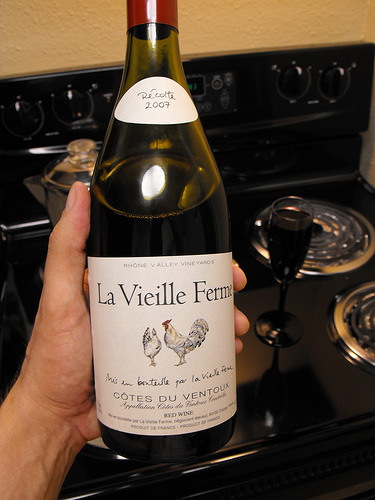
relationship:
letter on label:
[92, 280, 106, 304] [113, 77, 198, 123]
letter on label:
[106, 289, 115, 307] [113, 77, 198, 123]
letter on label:
[115, 281, 137, 302] [88, 251, 236, 434]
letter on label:
[195, 279, 205, 304] [88, 251, 236, 434]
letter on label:
[175, 288, 187, 304] [88, 251, 236, 434]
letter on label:
[143, 292, 155, 307] [88, 251, 236, 434]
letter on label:
[212, 286, 220, 300] [88, 251, 236, 434]